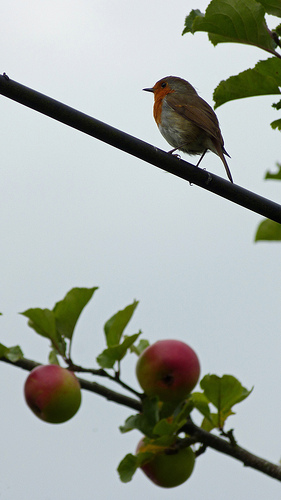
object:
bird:
[142, 75, 232, 185]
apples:
[135, 339, 200, 405]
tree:
[0, 338, 281, 487]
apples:
[138, 432, 196, 490]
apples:
[24, 365, 81, 425]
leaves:
[52, 286, 98, 339]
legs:
[196, 148, 207, 166]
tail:
[221, 157, 234, 185]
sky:
[0, 0, 281, 499]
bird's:
[153, 102, 166, 141]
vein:
[218, 380, 220, 426]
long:
[166, 101, 216, 140]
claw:
[166, 153, 177, 169]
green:
[98, 332, 141, 368]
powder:
[0, 0, 181, 76]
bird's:
[161, 81, 165, 87]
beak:
[142, 88, 153, 92]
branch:
[0, 74, 281, 225]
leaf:
[200, 374, 254, 414]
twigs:
[67, 365, 144, 399]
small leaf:
[0, 344, 22, 365]